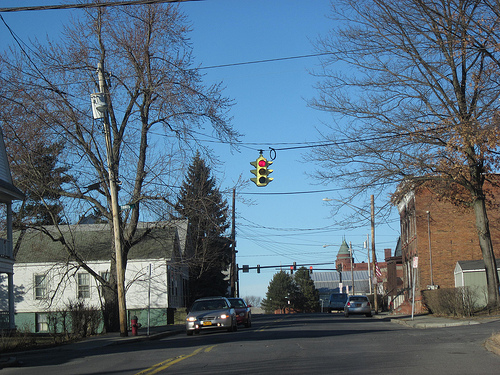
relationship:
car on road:
[185, 295, 237, 337] [57, 283, 462, 373]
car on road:
[226, 290, 253, 328] [57, 283, 462, 373]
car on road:
[343, 293, 374, 318] [57, 283, 462, 373]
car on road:
[328, 292, 349, 314] [57, 283, 462, 373]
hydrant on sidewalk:
[128, 314, 142, 336] [92, 319, 182, 345]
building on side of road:
[0, 222, 185, 334] [8, 307, 498, 374]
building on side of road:
[389, 171, 496, 308] [8, 307, 498, 374]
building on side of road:
[336, 232, 388, 270] [8, 307, 498, 374]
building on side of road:
[308, 270, 378, 308] [8, 307, 498, 374]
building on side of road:
[0, 127, 17, 337] [8, 307, 498, 374]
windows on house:
[33, 269, 121, 306] [1, 217, 190, 333]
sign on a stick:
[401, 238, 427, 278] [403, 250, 423, 330]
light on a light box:
[260, 159, 267, 168] [249, 154, 274, 187]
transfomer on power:
[89, 90, 112, 120] [40, 26, 195, 300]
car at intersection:
[187, 295, 234, 337] [175, 292, 487, 371]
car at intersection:
[226, 290, 253, 328] [175, 292, 487, 371]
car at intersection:
[344, 289, 371, 323] [175, 292, 487, 371]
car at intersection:
[322, 286, 347, 314] [175, 292, 487, 371]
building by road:
[0, 222, 185, 334] [0, 312, 499, 373]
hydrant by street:
[131, 315, 142, 335] [1, 305, 498, 373]